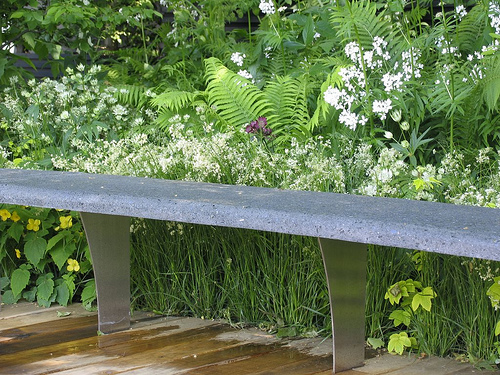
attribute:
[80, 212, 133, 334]
leg — metal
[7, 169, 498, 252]
seat — concrete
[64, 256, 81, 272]
flowers — yellow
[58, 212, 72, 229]
flowers — yellow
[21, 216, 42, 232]
flowers — yellow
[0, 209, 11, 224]
flowers — yellow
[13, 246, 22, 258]
flowers — yellow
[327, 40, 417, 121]
flowers — white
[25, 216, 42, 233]
flowers — white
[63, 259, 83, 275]
flowers — white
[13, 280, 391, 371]
deck — wet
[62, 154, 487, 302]
bench — concrete, metal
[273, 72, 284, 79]
leaf — green